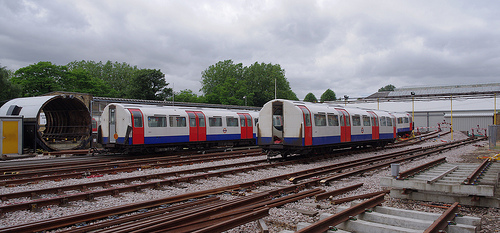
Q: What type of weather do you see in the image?
A: It is overcast.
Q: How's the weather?
A: It is overcast.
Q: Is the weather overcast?
A: Yes, it is overcast.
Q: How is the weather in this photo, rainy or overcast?
A: It is overcast.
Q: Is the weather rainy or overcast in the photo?
A: It is overcast.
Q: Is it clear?
A: No, it is overcast.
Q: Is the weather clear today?
A: No, it is overcast.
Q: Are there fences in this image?
A: No, there are no fences.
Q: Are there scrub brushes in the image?
A: No, there are no scrub brushes.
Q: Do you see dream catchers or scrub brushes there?
A: No, there are no scrub brushes or dream catchers.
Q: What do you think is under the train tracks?
A: The gravel is under the train tracks.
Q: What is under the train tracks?
A: The gravel is under the train tracks.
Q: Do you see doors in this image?
A: Yes, there are doors.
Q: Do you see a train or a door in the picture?
A: Yes, there are doors.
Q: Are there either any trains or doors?
A: Yes, there are doors.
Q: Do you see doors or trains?
A: Yes, there are doors.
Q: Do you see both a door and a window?
A: Yes, there are both a door and a window.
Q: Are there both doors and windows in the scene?
A: Yes, there are both doors and windows.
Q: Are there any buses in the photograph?
A: No, there are no buses.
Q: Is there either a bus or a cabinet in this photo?
A: No, there are no buses or cabinets.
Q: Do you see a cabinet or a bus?
A: No, there are no buses or cabinets.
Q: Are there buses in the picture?
A: No, there are no buses.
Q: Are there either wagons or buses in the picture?
A: No, there are no buses or wagons.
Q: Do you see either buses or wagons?
A: No, there are no buses or wagons.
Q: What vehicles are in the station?
A: The vehicles are cars.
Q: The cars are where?
A: The cars are in the station.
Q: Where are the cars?
A: The cars are in the station.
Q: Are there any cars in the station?
A: Yes, there are cars in the station.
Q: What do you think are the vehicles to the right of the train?
A: The vehicles are cars.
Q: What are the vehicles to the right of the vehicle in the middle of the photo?
A: The vehicles are cars.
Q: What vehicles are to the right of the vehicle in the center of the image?
A: The vehicles are cars.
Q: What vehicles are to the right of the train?
A: The vehicles are cars.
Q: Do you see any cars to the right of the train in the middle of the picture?
A: Yes, there are cars to the right of the train.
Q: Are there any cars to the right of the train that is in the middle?
A: Yes, there are cars to the right of the train.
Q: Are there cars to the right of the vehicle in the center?
A: Yes, there are cars to the right of the train.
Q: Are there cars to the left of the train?
A: No, the cars are to the right of the train.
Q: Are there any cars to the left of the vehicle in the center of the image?
A: No, the cars are to the right of the train.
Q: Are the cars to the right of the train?
A: Yes, the cars are to the right of the train.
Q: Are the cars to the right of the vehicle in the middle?
A: Yes, the cars are to the right of the train.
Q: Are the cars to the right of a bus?
A: No, the cars are to the right of the train.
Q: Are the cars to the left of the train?
A: No, the cars are to the right of the train.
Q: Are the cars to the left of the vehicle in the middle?
A: No, the cars are to the right of the train.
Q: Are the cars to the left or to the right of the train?
A: The cars are to the right of the train.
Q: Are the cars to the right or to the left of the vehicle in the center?
A: The cars are to the right of the train.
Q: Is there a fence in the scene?
A: No, there are no fences.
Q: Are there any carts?
A: No, there are no carts.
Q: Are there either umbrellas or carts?
A: No, there are no carts or umbrellas.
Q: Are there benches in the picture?
A: No, there are no benches.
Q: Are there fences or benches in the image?
A: No, there are no benches or fences.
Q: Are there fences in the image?
A: No, there are no fences.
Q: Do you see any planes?
A: No, there are no planes.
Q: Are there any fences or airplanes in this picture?
A: No, there are no airplanes or fences.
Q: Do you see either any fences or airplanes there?
A: No, there are no airplanes or fences.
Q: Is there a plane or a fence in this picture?
A: No, there are no airplanes or fences.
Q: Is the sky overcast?
A: Yes, the sky is overcast.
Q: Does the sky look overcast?
A: Yes, the sky is overcast.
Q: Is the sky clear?
A: No, the sky is overcast.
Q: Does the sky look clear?
A: No, the sky is overcast.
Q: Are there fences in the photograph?
A: No, there are no fences.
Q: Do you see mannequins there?
A: No, there are no mannequins.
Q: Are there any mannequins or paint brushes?
A: No, there are no mannequins or paint brushes.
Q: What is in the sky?
A: The clouds are in the sky.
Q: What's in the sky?
A: The clouds are in the sky.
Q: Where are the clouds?
A: The clouds are in the sky.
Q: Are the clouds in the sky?
A: Yes, the clouds are in the sky.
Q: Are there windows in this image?
A: Yes, there are windows.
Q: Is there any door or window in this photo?
A: Yes, there are windows.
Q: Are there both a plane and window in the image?
A: No, there are windows but no airplanes.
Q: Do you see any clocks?
A: No, there are no clocks.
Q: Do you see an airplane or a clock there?
A: No, there are no clocks or airplanes.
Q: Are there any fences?
A: No, there are no fences.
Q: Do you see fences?
A: No, there are no fences.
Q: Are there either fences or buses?
A: No, there are no fences or buses.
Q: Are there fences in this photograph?
A: No, there are no fences.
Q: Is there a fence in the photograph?
A: No, there are no fences.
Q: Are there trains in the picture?
A: Yes, there is a train.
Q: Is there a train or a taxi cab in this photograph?
A: Yes, there is a train.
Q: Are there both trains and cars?
A: Yes, there are both a train and cars.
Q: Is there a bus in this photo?
A: No, there are no buses.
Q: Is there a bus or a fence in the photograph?
A: No, there are no buses or fences.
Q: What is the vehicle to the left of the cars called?
A: The vehicle is a train.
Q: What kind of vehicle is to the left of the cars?
A: The vehicle is a train.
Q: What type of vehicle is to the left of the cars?
A: The vehicle is a train.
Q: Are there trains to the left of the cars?
A: Yes, there is a train to the left of the cars.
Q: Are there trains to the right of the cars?
A: No, the train is to the left of the cars.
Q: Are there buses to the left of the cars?
A: No, there is a train to the left of the cars.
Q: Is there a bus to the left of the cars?
A: No, there is a train to the left of the cars.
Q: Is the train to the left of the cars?
A: Yes, the train is to the left of the cars.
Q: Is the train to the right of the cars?
A: No, the train is to the left of the cars.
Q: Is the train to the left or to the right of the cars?
A: The train is to the left of the cars.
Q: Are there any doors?
A: Yes, there are doors.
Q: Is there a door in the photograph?
A: Yes, there are doors.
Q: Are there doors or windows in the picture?
A: Yes, there are doors.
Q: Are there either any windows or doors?
A: Yes, there are doors.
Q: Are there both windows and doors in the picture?
A: Yes, there are both doors and a window.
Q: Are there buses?
A: No, there are no buses.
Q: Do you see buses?
A: No, there are no buses.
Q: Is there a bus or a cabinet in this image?
A: No, there are no buses or cabinets.